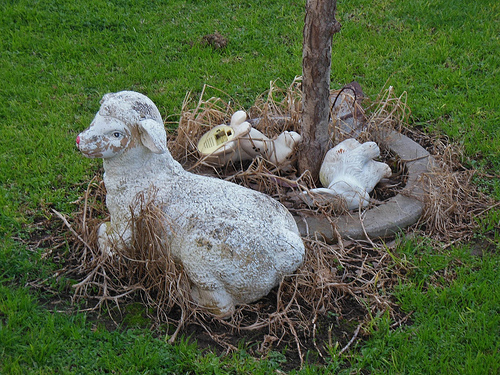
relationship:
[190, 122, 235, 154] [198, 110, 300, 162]
bottom of bunny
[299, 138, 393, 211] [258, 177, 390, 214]
bunny on sticks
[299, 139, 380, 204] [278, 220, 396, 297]
bunny on sticks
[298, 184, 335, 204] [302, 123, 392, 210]
ear lying on side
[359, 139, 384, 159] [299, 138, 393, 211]
paw side laying bunny